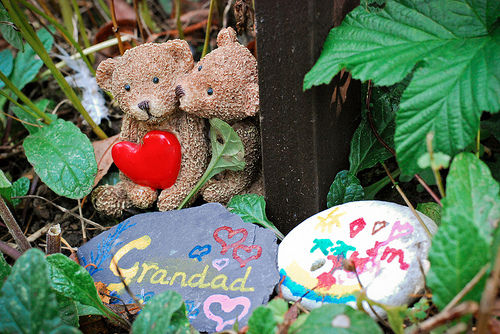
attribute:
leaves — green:
[21, 109, 129, 222]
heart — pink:
[202, 293, 250, 330]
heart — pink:
[382, 220, 412, 242]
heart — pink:
[211, 256, 230, 269]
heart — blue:
[187, 243, 211, 260]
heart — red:
[105, 125, 181, 194]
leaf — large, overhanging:
[302, 1, 497, 186]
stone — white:
[274, 188, 466, 314]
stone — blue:
[67, 195, 289, 332]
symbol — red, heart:
[78, 116, 188, 211]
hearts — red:
[208, 223, 265, 271]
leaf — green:
[420, 210, 495, 324]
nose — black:
[136, 99, 151, 114]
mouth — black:
[135, 111, 164, 123]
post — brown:
[253, 0, 340, 242]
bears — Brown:
[89, 34, 280, 224]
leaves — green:
[306, 8, 498, 185]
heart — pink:
[199, 290, 258, 332]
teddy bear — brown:
[86, 35, 203, 217]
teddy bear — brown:
[171, 25, 258, 202]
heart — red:
[110, 128, 180, 188]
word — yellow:
[98, 232, 253, 303]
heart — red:
[212, 227, 243, 247]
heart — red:
[234, 247, 255, 267]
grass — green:
[2, 1, 224, 137]